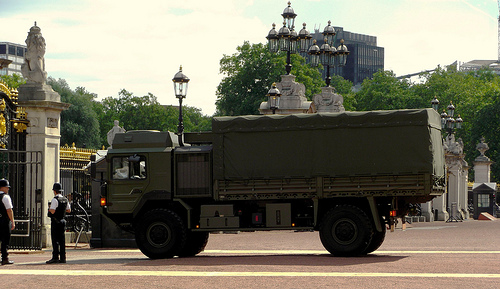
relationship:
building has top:
[288, 26, 385, 84] [331, 25, 388, 55]